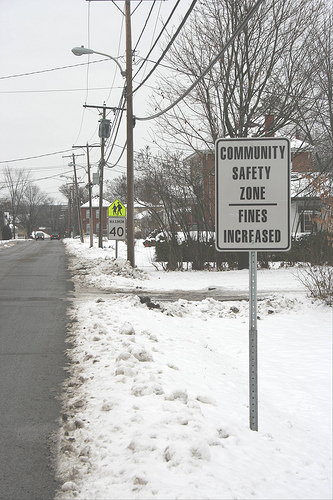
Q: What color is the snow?
A: White.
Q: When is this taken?
A: During the day.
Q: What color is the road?
A: Black.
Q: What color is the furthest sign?
A: Yellow.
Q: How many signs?
A: Two.